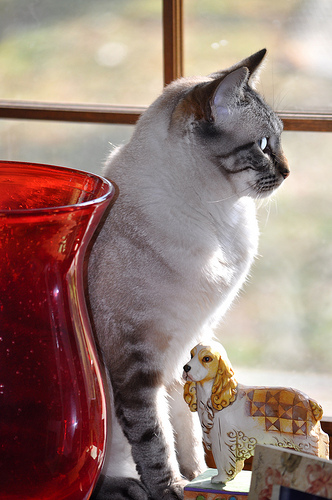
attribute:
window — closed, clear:
[1, 3, 331, 452]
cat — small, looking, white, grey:
[95, 47, 309, 491]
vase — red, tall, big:
[0, 154, 121, 499]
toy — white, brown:
[173, 343, 331, 481]